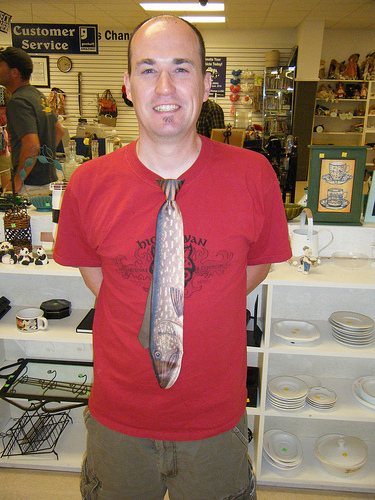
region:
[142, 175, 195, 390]
this tie looks like a dead fish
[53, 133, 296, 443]
man wearing a red t-shirt and a fish tie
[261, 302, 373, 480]
ceramicware for sale in a shop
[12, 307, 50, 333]
decorative cup for sale at a shop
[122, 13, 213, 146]
this man is bald and smiling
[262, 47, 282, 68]
vegetable steamer for sale in a shop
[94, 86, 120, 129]
purses for sale in a shop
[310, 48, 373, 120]
dolls for sale in a shop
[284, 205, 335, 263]
watering can for sale in a shop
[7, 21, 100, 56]
Customer Service sign posted in a shop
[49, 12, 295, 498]
man standing in a store wearing a fish tie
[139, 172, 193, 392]
fish tie on a man in a red shirt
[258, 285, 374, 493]
dishes on shelves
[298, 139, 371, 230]
coffee cup art on a plaque on a shelf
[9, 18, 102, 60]
customer service sign in a store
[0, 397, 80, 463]
rack on a shelf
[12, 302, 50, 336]
coffee mug on a shelf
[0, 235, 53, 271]
ceramic pandas on a shelf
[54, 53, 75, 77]
clock on a wall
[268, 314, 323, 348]
white plate on a shelf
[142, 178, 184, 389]
fish theme neck tie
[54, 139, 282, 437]
red cotton tee shirt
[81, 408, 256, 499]
grey cotton cargo pants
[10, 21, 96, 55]
black and white sign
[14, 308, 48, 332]
soup mug on shelf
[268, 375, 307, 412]
white plates on shelf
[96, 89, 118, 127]
tote bags on wall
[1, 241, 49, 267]
panda figures on shelf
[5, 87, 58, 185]
grey cotton tee shirt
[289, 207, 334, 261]
white metal watering can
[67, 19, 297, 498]
THIS IS A MAN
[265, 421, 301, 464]
this is a plate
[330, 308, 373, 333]
this is a plate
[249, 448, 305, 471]
this is a plate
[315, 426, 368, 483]
this is a plate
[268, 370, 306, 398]
this is a plate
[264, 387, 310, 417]
this is a plate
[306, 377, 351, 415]
this is a plate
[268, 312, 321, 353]
this is a plate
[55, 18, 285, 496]
man wearing red shirt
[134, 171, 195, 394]
clip on necktie man is wearing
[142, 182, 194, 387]
necktie with fish print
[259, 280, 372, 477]
white shelves with white plates on them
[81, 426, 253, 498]
pants of man in red shirt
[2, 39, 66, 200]
man standing behind white shelves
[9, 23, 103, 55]
white lettering on black sign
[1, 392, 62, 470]
wire rack on bottom shelf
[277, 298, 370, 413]
white plates on middle and top shelf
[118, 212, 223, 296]
black logo on red shirt